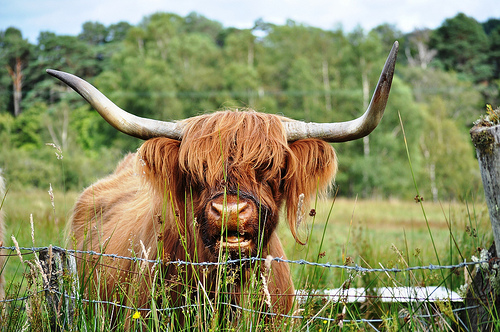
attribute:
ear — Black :
[284, 137, 338, 246]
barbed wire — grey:
[0, 242, 498, 271]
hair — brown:
[56, 110, 338, 310]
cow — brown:
[40, 55, 389, 255]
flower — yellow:
[119, 301, 146, 321]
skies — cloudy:
[216, 0, 380, 27]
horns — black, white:
[6, 40, 448, 154]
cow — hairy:
[17, 38, 407, 324]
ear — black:
[140, 135, 180, 231]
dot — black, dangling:
[305, 204, 320, 221]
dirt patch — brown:
[363, 210, 458, 235]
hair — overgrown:
[123, 127, 195, 199]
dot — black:
[308, 204, 318, 217]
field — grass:
[9, 107, 499, 327]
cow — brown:
[29, 48, 447, 286]